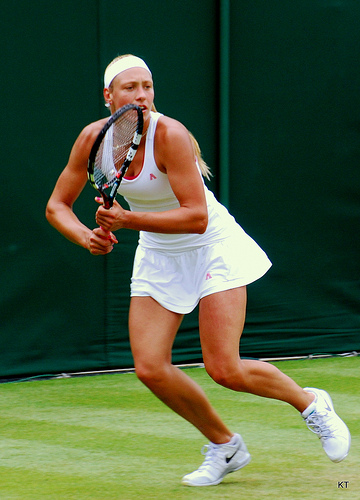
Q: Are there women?
A: Yes, there is a woman.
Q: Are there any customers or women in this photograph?
A: Yes, there is a woman.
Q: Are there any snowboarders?
A: No, there are no snowboarders.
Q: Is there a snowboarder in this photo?
A: No, there are no snowboarders.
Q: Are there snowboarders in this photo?
A: No, there are no snowboarders.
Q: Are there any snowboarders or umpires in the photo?
A: No, there are no snowboarders or umpires.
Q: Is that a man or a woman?
A: That is a woman.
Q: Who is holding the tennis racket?
A: The woman is holding the tennis racket.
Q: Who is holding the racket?
A: The woman is holding the tennis racket.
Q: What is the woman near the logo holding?
A: The woman is holding the tennis racket.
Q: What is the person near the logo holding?
A: The woman is holding the tennis racket.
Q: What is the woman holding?
A: The woman is holding the tennis racket.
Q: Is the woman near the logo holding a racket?
A: Yes, the woman is holding a racket.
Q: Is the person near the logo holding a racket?
A: Yes, the woman is holding a racket.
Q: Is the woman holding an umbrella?
A: No, the woman is holding a racket.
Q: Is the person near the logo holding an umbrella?
A: No, the woman is holding a racket.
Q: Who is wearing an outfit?
A: The woman is wearing an outfit.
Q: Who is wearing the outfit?
A: The woman is wearing an outfit.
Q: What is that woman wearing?
A: The woman is wearing an outfit.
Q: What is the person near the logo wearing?
A: The woman is wearing an outfit.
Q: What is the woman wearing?
A: The woman is wearing an outfit.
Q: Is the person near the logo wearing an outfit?
A: Yes, the woman is wearing an outfit.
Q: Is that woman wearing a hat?
A: No, the woman is wearing an outfit.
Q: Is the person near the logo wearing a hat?
A: No, the woman is wearing an outfit.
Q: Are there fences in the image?
A: No, there are no fences.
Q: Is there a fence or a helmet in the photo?
A: No, there are no fences or helmets.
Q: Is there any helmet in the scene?
A: No, there are no helmets.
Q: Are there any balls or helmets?
A: No, there are no helmets or balls.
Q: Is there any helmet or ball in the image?
A: No, there are no helmets or balls.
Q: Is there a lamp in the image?
A: No, there are no lamps.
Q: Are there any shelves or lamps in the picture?
A: No, there are no lamps or shelves.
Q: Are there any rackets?
A: Yes, there is a racket.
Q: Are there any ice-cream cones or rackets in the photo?
A: Yes, there is a racket.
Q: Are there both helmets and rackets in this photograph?
A: No, there is a racket but no helmets.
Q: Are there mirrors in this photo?
A: No, there are no mirrors.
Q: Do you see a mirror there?
A: No, there are no mirrors.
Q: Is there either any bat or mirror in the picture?
A: No, there are no mirrors or bats.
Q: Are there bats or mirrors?
A: No, there are no mirrors or bats.